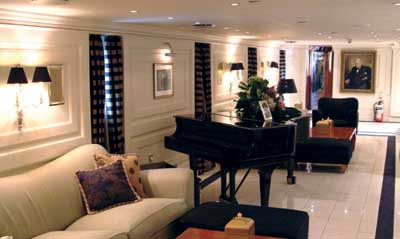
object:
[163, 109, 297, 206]
blue sky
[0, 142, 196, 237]
sofa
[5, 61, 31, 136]
light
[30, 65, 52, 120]
light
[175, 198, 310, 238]
coffee table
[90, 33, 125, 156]
curtain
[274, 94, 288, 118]
person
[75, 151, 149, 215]
pillows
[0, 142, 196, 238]
couch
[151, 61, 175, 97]
picture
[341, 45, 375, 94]
picture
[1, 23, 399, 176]
wall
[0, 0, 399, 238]
house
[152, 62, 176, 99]
frame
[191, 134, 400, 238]
floors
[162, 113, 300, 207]
piano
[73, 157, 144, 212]
pillow